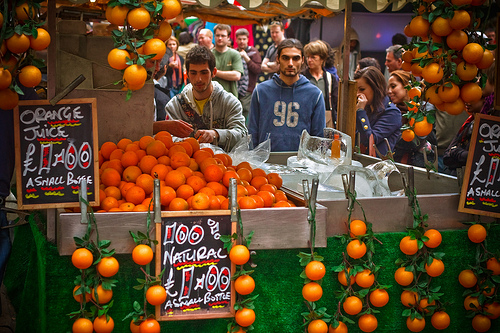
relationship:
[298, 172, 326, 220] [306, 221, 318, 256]
scissor hook holds vine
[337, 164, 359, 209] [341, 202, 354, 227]
scissor hook holds vine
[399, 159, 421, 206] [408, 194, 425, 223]
scissor hook holds vine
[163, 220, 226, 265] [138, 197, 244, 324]
100% natural on sign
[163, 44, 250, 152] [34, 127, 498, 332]
man shopping at an orange stand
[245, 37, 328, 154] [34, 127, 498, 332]
people shopping at an orange stand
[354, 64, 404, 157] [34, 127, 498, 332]
people shopping at an orange stand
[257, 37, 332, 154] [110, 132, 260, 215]
people with oranges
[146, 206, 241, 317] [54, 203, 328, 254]
sign on stand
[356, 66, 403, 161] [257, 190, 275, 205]
people with oranges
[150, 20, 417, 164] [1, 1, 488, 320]
people at stand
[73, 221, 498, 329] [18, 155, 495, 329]
oranges at stand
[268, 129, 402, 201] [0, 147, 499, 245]
equipment on stand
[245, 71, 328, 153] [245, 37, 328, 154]
shirt on people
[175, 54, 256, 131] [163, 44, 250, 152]
man with man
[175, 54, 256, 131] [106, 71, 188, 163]
man with stand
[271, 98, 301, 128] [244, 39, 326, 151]
96 on shirt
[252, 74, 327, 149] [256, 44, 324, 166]
shirt on man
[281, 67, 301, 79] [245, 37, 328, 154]
beard on people